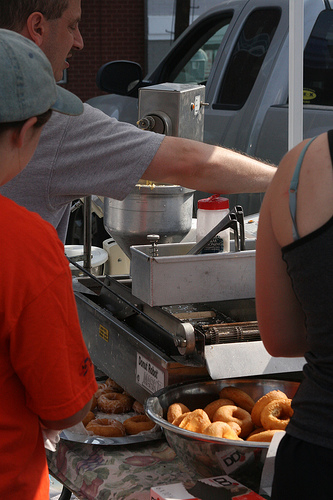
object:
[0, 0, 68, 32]
hair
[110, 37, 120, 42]
brick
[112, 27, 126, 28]
cement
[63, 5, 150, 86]
brick building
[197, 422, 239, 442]
donuts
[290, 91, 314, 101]
sticker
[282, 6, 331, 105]
window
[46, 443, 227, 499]
tablecloth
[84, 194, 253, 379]
doughnut fryer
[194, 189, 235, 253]
bottle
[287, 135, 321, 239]
strap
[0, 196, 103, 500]
shirt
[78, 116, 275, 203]
arm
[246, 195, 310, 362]
arm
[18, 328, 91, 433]
arm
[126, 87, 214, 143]
mixer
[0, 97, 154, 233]
shirt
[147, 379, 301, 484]
bowl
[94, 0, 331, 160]
silver truck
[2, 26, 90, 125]
cap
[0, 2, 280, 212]
man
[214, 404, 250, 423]
doughnuts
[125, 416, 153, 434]
doughnuts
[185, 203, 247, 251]
handles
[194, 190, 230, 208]
red lid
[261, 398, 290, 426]
doughnut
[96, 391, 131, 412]
doughnut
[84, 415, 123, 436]
doughnut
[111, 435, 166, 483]
patter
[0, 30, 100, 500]
person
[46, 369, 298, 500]
table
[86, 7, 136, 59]
part